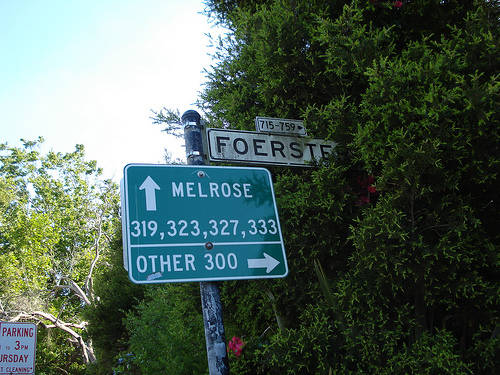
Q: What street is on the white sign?
A: Foerste.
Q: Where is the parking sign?
A: The bottom left.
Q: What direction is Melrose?
A: Straight ahead.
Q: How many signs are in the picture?
A: Three.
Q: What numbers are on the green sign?
A: 319, 323,327, 333, 300.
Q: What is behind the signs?
A: Trees.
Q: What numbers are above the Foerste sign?
A: 715, 759.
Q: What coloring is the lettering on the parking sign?
A: Red.